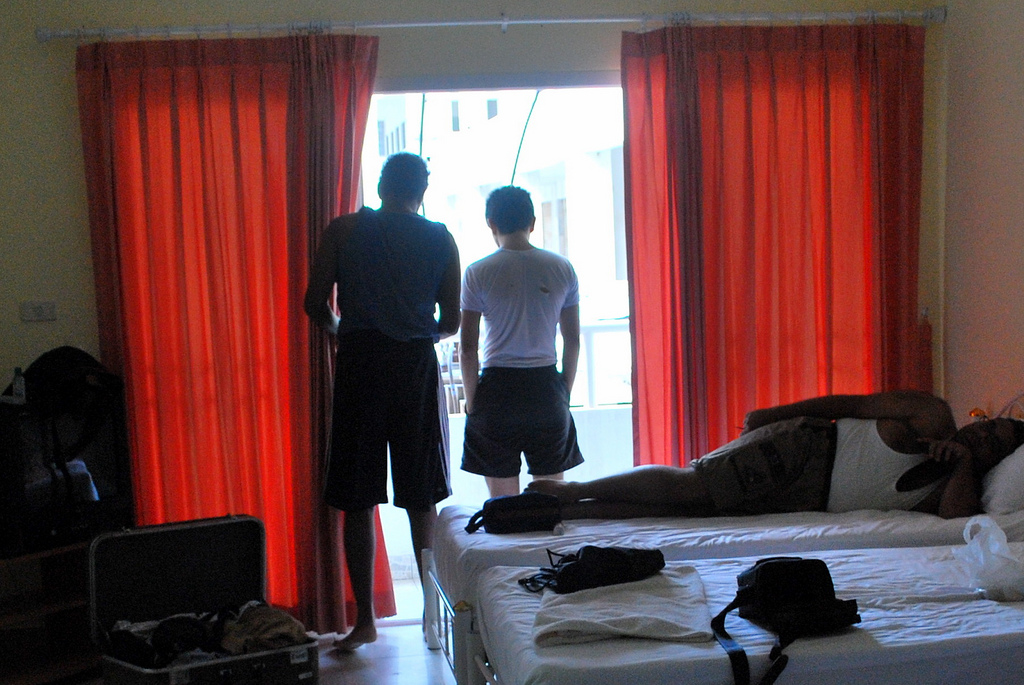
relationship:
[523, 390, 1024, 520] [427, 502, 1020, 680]
man in bed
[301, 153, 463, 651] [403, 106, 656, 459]
man standing at door way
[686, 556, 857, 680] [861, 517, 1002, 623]
bag on bed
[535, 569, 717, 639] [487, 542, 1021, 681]
towel on bed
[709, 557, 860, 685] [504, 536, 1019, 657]
bag on bed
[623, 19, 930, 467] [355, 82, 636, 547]
curtain covering window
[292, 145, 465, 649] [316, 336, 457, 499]
man wearing shorts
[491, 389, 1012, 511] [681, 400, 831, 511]
man wearing shorts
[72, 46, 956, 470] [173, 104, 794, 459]
curtain attached to window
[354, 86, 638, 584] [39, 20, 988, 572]
door way attached to building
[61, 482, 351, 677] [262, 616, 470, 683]
suitcase on top of floor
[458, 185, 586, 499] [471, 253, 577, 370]
man wearing shirt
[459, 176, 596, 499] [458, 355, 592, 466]
man wearing shorts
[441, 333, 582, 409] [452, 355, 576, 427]
hands are inside pockets